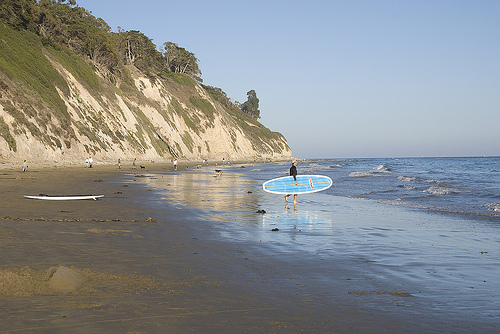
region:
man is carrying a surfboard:
[258, 168, 334, 209]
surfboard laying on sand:
[35, 190, 98, 220]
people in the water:
[205, 166, 233, 179]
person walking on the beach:
[17, 151, 39, 190]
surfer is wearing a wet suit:
[285, 164, 315, 180]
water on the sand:
[182, 167, 242, 259]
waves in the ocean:
[363, 159, 419, 197]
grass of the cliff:
[95, 93, 153, 134]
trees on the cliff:
[91, 36, 177, 71]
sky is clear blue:
[260, 6, 453, 75]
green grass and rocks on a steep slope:
[0, 56, 296, 156]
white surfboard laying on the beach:
[0, 180, 122, 207]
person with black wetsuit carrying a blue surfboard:
[260, 148, 340, 207]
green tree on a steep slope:
[224, 80, 268, 125]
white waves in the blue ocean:
[362, 157, 470, 199]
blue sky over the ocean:
[168, 0, 464, 54]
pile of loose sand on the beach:
[0, 261, 142, 315]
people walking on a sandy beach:
[0, 153, 187, 173]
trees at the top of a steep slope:
[21, 0, 173, 71]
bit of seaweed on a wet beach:
[334, 276, 428, 302]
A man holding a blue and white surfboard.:
[258, 153, 331, 209]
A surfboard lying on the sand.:
[22, 189, 107, 204]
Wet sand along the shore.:
[140, 155, 490, 315]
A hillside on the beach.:
[0, 7, 290, 170]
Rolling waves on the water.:
[255, 155, 495, 205]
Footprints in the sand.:
[10, 212, 166, 223]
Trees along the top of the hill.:
[0, 1, 265, 121]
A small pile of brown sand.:
[10, 260, 135, 291]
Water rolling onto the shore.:
[355, 192, 495, 215]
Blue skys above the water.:
[1, 0, 493, 160]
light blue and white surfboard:
[262, 174, 331, 196]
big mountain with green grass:
[0, 3, 293, 164]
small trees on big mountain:
[2, 0, 262, 122]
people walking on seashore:
[19, 153, 211, 173]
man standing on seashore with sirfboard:
[282, 159, 301, 205]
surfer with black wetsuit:
[284, 158, 300, 203]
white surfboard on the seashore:
[24, 190, 104, 203]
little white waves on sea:
[306, 161, 464, 199]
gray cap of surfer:
[290, 155, 300, 165]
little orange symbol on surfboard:
[307, 176, 317, 191]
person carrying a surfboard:
[257, 147, 339, 212]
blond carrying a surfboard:
[254, 153, 333, 223]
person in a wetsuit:
[252, 152, 349, 217]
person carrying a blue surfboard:
[253, 150, 338, 217]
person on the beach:
[164, 140, 181, 193]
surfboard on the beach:
[16, 180, 105, 211]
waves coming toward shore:
[350, 158, 473, 220]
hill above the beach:
[0, 8, 294, 166]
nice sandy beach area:
[0, 216, 237, 329]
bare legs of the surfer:
[280, 188, 299, 210]